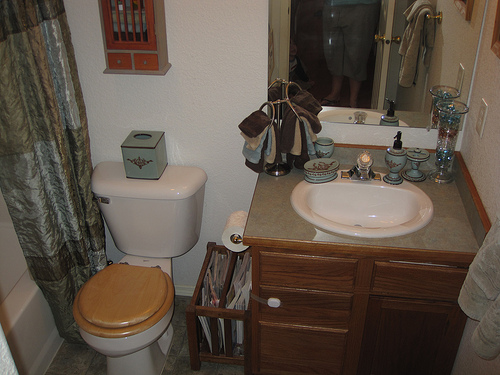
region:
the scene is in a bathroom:
[72, 17, 495, 359]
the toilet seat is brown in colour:
[74, 262, 194, 372]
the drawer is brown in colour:
[275, 245, 483, 372]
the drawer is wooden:
[263, 258, 426, 372]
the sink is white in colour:
[276, 160, 433, 255]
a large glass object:
[427, 93, 471, 187]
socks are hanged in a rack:
[213, 61, 318, 174]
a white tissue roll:
[213, 208, 255, 252]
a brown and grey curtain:
[14, 13, 89, 243]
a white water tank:
[93, 158, 206, 245]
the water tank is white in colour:
[86, 158, 215, 260]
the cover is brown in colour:
[58, 258, 210, 355]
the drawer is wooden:
[273, 263, 327, 372]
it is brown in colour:
[282, 273, 384, 370]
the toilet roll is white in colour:
[212, 196, 255, 255]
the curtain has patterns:
[6, 78, 88, 252]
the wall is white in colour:
[191, 15, 237, 151]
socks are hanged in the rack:
[236, 83, 314, 191]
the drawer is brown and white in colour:
[95, 3, 201, 105]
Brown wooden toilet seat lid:
[68, 258, 177, 343]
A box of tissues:
[118, 124, 172, 186]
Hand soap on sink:
[381, 121, 411, 196]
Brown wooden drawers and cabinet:
[248, 245, 470, 373]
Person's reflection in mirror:
[308, 0, 386, 113]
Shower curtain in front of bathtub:
[2, 1, 110, 373]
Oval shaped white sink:
[286, 161, 439, 244]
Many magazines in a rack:
[182, 234, 255, 372]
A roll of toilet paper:
[217, 207, 253, 255]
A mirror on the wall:
[265, 0, 490, 134]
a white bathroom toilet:
[39, 91, 349, 373]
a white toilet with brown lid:
[25, 128, 200, 352]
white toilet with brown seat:
[47, 88, 274, 364]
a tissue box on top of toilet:
[36, 115, 215, 355]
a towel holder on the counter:
[225, 55, 495, 322]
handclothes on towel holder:
[249, 58, 482, 263]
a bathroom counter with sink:
[230, 62, 494, 342]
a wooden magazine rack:
[104, 192, 276, 372]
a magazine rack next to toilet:
[24, 106, 304, 374]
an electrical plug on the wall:
[458, 76, 499, 150]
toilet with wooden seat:
[70, 173, 197, 348]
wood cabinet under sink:
[236, 153, 498, 351]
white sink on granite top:
[288, 148, 440, 255]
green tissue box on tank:
[103, 113, 173, 186]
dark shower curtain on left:
[3, 55, 139, 320]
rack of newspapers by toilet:
[191, 238, 266, 337]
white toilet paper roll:
[223, 190, 272, 257]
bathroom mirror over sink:
[263, 18, 498, 148]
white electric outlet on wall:
[454, 81, 499, 136]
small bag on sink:
[245, 88, 333, 180]